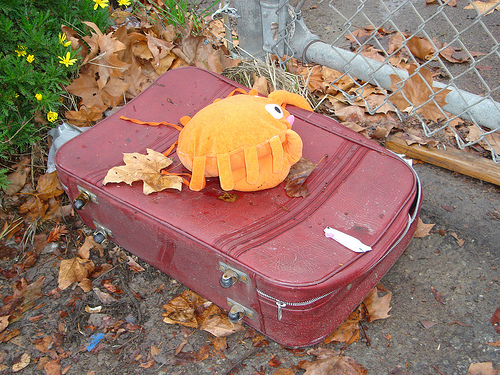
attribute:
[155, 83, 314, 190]
stuffed animal — orange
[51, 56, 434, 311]
suitcase — red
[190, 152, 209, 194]
leg — orange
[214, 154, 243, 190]
leg — orange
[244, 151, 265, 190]
leg — orange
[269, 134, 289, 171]
leg — orange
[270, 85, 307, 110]
leg — orange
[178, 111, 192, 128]
leg — orange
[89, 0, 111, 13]
flower — yellow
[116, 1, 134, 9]
flower — yellow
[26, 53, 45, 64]
flower — yellow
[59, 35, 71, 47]
flower — yellow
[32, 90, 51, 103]
flower — yellow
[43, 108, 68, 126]
flower — yellow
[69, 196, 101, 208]
wheel — black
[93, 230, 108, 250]
wheel — black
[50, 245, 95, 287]
leaf — brown